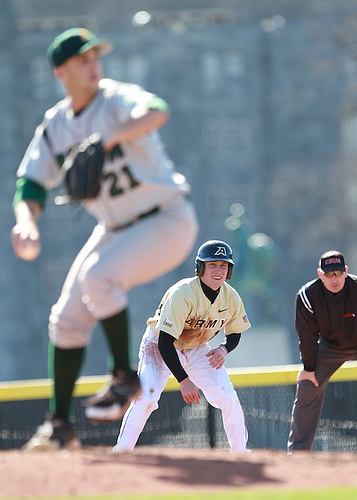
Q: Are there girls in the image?
A: No, there are no girls.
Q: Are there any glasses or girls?
A: No, there are no girls or glasses.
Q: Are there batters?
A: No, there are no batters.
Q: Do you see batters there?
A: No, there are no batters.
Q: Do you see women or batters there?
A: No, there are no batters or women.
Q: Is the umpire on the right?
A: Yes, the umpire is on the right of the image.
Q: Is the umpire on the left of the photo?
A: No, the umpire is on the right of the image.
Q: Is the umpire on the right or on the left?
A: The umpire is on the right of the image.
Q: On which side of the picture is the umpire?
A: The umpire is on the right of the image.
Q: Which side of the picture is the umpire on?
A: The umpire is on the right of the image.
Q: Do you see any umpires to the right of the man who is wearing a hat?
A: Yes, there is an umpire to the right of the man.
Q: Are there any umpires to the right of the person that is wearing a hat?
A: Yes, there is an umpire to the right of the man.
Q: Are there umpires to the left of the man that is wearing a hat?
A: No, the umpire is to the right of the man.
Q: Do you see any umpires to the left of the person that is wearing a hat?
A: No, the umpire is to the right of the man.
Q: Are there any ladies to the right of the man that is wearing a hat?
A: No, there is an umpire to the right of the man.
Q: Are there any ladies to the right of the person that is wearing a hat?
A: No, there is an umpire to the right of the man.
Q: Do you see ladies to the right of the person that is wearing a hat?
A: No, there is an umpire to the right of the man.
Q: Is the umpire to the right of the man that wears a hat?
A: Yes, the umpire is to the right of the man.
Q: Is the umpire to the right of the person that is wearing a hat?
A: Yes, the umpire is to the right of the man.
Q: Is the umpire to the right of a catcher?
A: No, the umpire is to the right of the man.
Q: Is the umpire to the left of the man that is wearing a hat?
A: No, the umpire is to the right of the man.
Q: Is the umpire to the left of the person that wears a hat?
A: No, the umpire is to the right of the man.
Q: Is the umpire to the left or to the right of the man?
A: The umpire is to the right of the man.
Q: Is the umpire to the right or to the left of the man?
A: The umpire is to the right of the man.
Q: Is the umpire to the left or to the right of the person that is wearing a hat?
A: The umpire is to the right of the man.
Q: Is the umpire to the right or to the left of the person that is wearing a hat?
A: The umpire is to the right of the man.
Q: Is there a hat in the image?
A: Yes, there is a hat.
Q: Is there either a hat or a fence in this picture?
A: Yes, there is a hat.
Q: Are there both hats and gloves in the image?
A: Yes, there are both a hat and gloves.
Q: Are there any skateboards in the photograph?
A: No, there are no skateboards.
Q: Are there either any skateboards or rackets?
A: No, there are no skateboards or rackets.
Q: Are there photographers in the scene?
A: No, there are no photographers.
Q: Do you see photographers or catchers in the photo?
A: No, there are no photographers or catchers.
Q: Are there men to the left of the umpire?
A: Yes, there is a man to the left of the umpire.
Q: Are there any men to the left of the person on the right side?
A: Yes, there is a man to the left of the umpire.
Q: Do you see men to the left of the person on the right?
A: Yes, there is a man to the left of the umpire.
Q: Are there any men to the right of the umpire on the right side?
A: No, the man is to the left of the umpire.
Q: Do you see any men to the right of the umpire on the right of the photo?
A: No, the man is to the left of the umpire.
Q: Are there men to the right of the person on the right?
A: No, the man is to the left of the umpire.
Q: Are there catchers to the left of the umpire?
A: No, there is a man to the left of the umpire.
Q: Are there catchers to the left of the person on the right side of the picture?
A: No, there is a man to the left of the umpire.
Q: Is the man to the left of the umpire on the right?
A: Yes, the man is to the left of the umpire.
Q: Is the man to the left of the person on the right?
A: Yes, the man is to the left of the umpire.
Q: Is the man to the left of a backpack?
A: No, the man is to the left of the umpire.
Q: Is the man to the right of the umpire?
A: No, the man is to the left of the umpire.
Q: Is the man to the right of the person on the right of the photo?
A: No, the man is to the left of the umpire.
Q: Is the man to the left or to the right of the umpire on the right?
A: The man is to the left of the umpire.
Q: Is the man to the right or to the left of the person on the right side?
A: The man is to the left of the umpire.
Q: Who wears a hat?
A: The man wears a hat.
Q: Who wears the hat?
A: The man wears a hat.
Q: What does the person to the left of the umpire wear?
A: The man wears a hat.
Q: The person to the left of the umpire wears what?
A: The man wears a hat.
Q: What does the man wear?
A: The man wears a hat.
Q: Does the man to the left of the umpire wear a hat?
A: Yes, the man wears a hat.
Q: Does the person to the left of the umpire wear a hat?
A: Yes, the man wears a hat.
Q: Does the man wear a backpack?
A: No, the man wears a hat.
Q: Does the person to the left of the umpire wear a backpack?
A: No, the man wears a hat.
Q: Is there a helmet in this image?
A: Yes, there is a helmet.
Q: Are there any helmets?
A: Yes, there is a helmet.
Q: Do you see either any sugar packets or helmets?
A: Yes, there is a helmet.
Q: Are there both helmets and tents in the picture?
A: No, there is a helmet but no tents.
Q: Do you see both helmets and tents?
A: No, there is a helmet but no tents.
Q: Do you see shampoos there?
A: No, there are no shampoos.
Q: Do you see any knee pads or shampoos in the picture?
A: No, there are no shampoos or knee pads.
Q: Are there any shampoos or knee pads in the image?
A: No, there are no shampoos or knee pads.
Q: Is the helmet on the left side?
A: Yes, the helmet is on the left of the image.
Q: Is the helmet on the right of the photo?
A: No, the helmet is on the left of the image.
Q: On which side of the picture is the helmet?
A: The helmet is on the left of the image.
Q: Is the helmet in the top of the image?
A: Yes, the helmet is in the top of the image.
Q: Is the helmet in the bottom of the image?
A: No, the helmet is in the top of the image.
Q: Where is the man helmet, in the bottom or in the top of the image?
A: The helmet is in the top of the image.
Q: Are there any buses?
A: No, there are no buses.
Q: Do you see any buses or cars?
A: No, there are no buses or cars.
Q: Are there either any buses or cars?
A: No, there are no buses or cars.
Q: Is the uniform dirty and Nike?
A: Yes, the uniform is dirty and nike.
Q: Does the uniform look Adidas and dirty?
A: No, the uniform is dirty but nike.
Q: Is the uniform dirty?
A: Yes, the uniform is dirty.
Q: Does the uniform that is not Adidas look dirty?
A: Yes, the uniform is dirty.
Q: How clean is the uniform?
A: The uniform is dirty.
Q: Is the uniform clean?
A: No, the uniform is dirty.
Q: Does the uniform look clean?
A: No, the uniform is dirty.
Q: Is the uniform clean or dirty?
A: The uniform is dirty.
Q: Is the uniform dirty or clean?
A: The uniform is dirty.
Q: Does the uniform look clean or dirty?
A: The uniform is dirty.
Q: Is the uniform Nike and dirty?
A: Yes, the uniform is Nike and dirty.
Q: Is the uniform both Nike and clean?
A: No, the uniform is Nike but dirty.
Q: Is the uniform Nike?
A: Yes, the uniform is nike.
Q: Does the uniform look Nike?
A: Yes, the uniform is nike.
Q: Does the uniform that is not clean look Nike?
A: Yes, the uniform is nike.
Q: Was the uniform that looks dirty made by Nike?
A: Yes, the uniform was made by nike.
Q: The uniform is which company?
A: The uniform is nike.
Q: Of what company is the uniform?
A: The uniform is nike.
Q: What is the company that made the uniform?
A: The company that made the uniform is nike.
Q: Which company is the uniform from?
A: The uniform is from nike.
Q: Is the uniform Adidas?
A: No, the uniform is nike.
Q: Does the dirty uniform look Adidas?
A: No, the uniform is nike.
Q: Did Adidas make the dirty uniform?
A: No, the uniform was made by nike.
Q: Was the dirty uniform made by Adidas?
A: No, the uniform was made by nike.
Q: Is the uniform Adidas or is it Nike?
A: The uniform is nike.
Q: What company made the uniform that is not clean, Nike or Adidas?
A: The uniform was made nike.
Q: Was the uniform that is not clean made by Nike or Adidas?
A: The uniform was made nike.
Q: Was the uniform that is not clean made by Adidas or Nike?
A: The uniform was made nike.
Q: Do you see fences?
A: Yes, there is a fence.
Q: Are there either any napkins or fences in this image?
A: Yes, there is a fence.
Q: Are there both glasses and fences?
A: No, there is a fence but no glasses.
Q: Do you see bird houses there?
A: No, there are no bird houses.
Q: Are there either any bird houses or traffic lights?
A: No, there are no bird houses or traffic lights.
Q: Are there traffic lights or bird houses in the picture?
A: No, there are no bird houses or traffic lights.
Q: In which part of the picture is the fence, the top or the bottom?
A: The fence is in the bottom of the image.